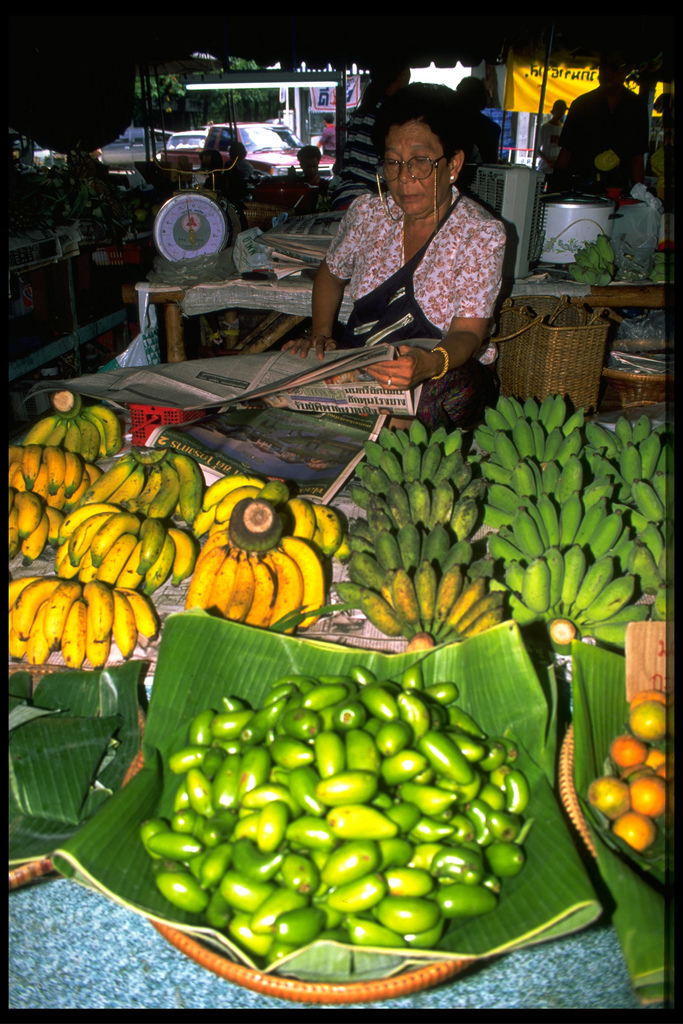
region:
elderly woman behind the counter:
[353, 94, 525, 365]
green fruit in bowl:
[156, 686, 543, 969]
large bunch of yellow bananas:
[175, 466, 339, 633]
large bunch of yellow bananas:
[73, 515, 202, 600]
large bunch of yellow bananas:
[96, 435, 191, 501]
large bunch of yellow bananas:
[20, 391, 115, 462]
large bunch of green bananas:
[530, 550, 656, 639]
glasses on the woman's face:
[366, 146, 445, 186]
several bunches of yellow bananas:
[17, 404, 337, 635]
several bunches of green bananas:
[337, 396, 660, 623]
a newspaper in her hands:
[100, 328, 439, 408]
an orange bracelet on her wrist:
[424, 345, 454, 388]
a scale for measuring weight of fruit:
[146, 184, 234, 273]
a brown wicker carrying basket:
[504, 283, 616, 422]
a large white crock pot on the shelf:
[541, 183, 625, 272]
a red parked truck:
[162, 110, 337, 194]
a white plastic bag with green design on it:
[74, 278, 176, 385]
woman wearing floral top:
[274, 80, 511, 392]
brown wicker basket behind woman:
[276, 76, 614, 429]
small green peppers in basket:
[114, 659, 533, 1003]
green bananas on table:
[12, 391, 676, 1007]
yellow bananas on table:
[10, 390, 675, 1005]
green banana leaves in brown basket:
[7, 655, 151, 890]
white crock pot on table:
[137, 180, 682, 365]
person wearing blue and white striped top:
[322, 59, 413, 201]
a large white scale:
[160, 198, 222, 259]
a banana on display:
[445, 508, 488, 575]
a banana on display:
[533, 495, 569, 575]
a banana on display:
[376, 524, 396, 564]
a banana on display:
[31, 519, 74, 574]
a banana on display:
[60, 560, 122, 657]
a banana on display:
[87, 488, 158, 607]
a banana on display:
[127, 448, 181, 533]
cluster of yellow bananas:
[10, 484, 62, 575]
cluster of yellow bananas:
[28, 384, 127, 460]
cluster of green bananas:
[491, 497, 648, 566]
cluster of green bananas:
[363, 444, 471, 486]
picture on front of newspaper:
[187, 383, 382, 507]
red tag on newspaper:
[121, 387, 195, 449]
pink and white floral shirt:
[330, 178, 509, 350]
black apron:
[357, 201, 452, 343]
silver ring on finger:
[380, 373, 396, 391]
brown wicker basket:
[494, 271, 614, 418]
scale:
[147, 194, 230, 264]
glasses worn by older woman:
[361, 152, 473, 194]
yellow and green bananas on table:
[114, 586, 151, 655]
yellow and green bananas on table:
[23, 575, 71, 650]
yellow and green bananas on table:
[58, 471, 123, 580]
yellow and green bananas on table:
[118, 512, 186, 588]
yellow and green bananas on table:
[98, 449, 196, 523]